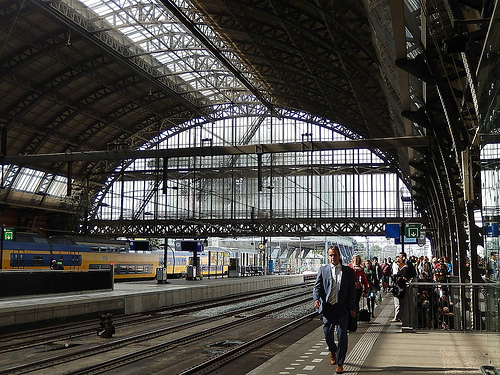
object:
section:
[295, 48, 351, 93]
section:
[16, 314, 115, 361]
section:
[195, 253, 229, 276]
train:
[2, 233, 278, 276]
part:
[364, 316, 374, 319]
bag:
[357, 306, 374, 326]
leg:
[321, 319, 334, 352]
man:
[312, 247, 359, 372]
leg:
[336, 317, 349, 361]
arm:
[310, 271, 322, 299]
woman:
[351, 248, 373, 312]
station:
[0, 0, 499, 370]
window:
[32, 255, 44, 265]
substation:
[3, 223, 293, 316]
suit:
[307, 264, 358, 323]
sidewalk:
[272, 341, 327, 371]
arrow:
[409, 230, 420, 238]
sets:
[182, 300, 288, 346]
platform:
[244, 291, 499, 374]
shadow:
[345, 359, 474, 372]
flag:
[382, 222, 402, 239]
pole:
[402, 219, 408, 254]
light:
[3, 233, 16, 242]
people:
[364, 259, 379, 314]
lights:
[130, 31, 147, 42]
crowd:
[355, 253, 446, 299]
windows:
[123, 264, 137, 274]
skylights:
[156, 49, 174, 66]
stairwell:
[408, 292, 472, 327]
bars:
[146, 115, 360, 150]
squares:
[301, 363, 318, 370]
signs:
[399, 224, 428, 244]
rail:
[0, 277, 351, 374]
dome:
[3, 0, 398, 126]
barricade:
[397, 281, 490, 326]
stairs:
[428, 297, 481, 322]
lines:
[291, 355, 312, 361]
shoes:
[331, 365, 345, 373]